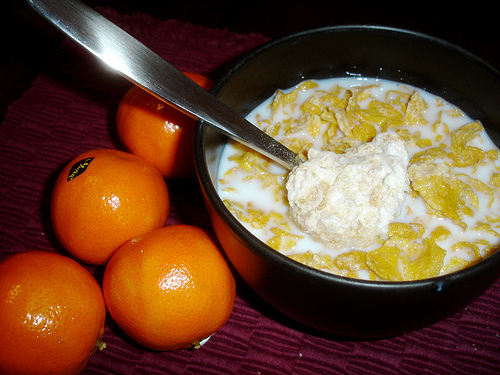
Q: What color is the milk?
A: White.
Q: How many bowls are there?
A: 1.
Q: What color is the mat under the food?
A: Burgundy.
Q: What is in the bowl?
A: Cereal.